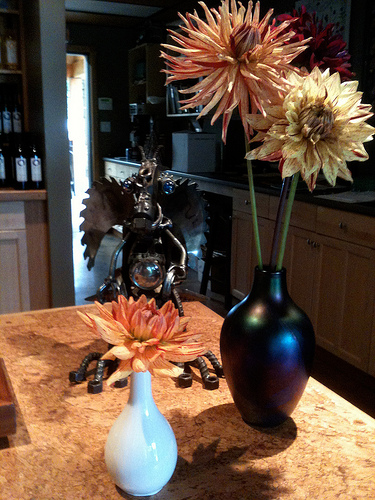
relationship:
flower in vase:
[76, 291, 208, 384] [96, 364, 177, 499]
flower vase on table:
[102, 364, 177, 496] [1, 300, 373, 497]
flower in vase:
[263, 66, 374, 269] [215, 261, 318, 438]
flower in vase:
[158, 1, 312, 271] [215, 261, 318, 438]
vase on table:
[215, 261, 318, 438] [1, 300, 373, 497]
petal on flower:
[147, 351, 184, 378] [76, 288, 208, 384]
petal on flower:
[73, 297, 206, 376] [102, 363, 132, 388]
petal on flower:
[86, 317, 129, 344] [59, 284, 210, 380]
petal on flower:
[150, 339, 207, 358] [73, 289, 208, 393]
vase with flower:
[215, 261, 318, 438] [245, 66, 374, 198]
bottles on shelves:
[5, 35, 43, 178] [1, 2, 42, 191]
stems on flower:
[231, 122, 297, 290] [245, 66, 374, 198]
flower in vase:
[245, 66, 374, 198] [219, 264, 323, 435]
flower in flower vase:
[76, 288, 208, 384] [104, 364, 178, 496]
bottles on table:
[9, 149, 43, 186] [1, 186, 46, 199]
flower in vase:
[275, 12, 347, 85] [209, 262, 322, 424]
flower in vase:
[245, 66, 374, 198] [213, 156, 316, 435]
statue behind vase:
[73, 150, 213, 295] [217, 262, 318, 426]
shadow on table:
[182, 429, 286, 493] [1, 300, 373, 497]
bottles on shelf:
[3, 141, 45, 187] [2, 178, 48, 319]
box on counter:
[165, 126, 223, 179] [161, 172, 234, 259]